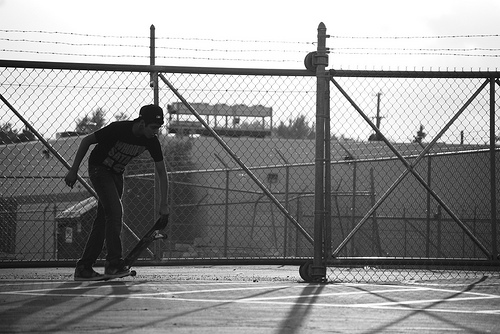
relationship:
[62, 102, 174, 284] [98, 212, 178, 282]
boy holding skateboard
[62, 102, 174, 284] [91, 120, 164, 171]
boy wearing shirt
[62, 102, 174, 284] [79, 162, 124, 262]
boy wearing jeans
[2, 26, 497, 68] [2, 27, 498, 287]
wire on top fence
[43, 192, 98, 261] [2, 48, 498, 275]
dumpster behind fence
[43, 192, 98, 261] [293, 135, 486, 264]
dumpster behind fence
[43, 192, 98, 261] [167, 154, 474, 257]
dumpster behind fence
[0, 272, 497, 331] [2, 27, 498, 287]
shadow of fence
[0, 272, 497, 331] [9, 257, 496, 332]
shadow on ground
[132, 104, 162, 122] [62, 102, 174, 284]
black cap on boy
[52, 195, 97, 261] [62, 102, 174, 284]
dumpster behind boy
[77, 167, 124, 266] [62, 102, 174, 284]
jeans on boy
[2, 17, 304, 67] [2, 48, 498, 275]
barbed wire on top fence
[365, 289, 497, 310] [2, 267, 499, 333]
line painted on blacktop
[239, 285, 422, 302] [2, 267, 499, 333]
line painted on blacktop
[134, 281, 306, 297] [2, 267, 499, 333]
line painted on blacktop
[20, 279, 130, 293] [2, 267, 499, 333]
line painted on blacktop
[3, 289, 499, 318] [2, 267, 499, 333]
line painted on blacktop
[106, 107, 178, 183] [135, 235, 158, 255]
boy flipping skateboard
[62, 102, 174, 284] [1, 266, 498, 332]
boy skateboarding on ground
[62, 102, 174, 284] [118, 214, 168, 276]
boy holding skate board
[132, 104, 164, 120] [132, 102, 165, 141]
black cap on head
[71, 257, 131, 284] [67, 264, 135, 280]
shoes on man's feet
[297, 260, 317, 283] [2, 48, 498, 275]
wheel on fence